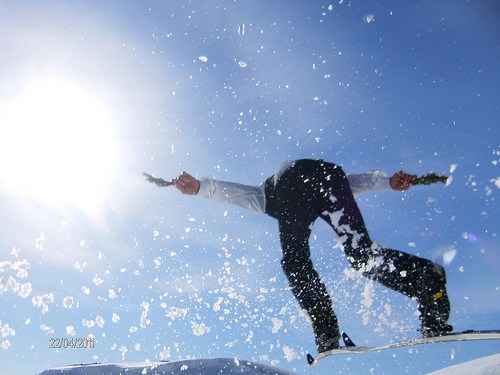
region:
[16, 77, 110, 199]
the sun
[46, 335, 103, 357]
date on the picture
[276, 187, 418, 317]
person is wearing pants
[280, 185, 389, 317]
the pants are black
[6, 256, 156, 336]
snow particles in the sky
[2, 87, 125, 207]
the sun is bright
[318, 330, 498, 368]
the ski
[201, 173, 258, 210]
white long sleeves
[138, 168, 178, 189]
person is carrying an object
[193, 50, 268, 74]
snow particles in the sky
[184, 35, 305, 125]
the sky is clear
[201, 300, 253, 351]
the sky is clear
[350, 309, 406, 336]
the sky is clear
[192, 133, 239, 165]
the sky is clear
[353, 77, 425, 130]
the sky is clear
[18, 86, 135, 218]
bright sun is shinning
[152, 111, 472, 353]
the man is skiing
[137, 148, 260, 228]
the hand of a man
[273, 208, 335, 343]
the leg of a man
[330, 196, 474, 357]
the leg of a man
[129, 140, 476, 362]
a man riding a snowboard.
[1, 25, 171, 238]
a sun in a blue sky.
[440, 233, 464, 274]
snow flying into the air.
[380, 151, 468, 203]
a right hand.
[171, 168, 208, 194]
a left hand.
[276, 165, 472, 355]
a pair of black pants.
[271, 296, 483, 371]
a board under a man's legs.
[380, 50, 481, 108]
a section of blue sky.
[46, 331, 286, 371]
a hill covered in snow.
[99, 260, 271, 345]
a section of flying snow.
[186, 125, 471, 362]
A person is skiing.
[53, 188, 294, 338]
It is snowing outside.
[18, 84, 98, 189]
The sun is shining.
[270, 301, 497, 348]
The man is on a snowboard.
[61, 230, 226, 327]
The snowflakes is white.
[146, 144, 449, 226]
The person is bend over.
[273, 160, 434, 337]
The person is wearing black pants.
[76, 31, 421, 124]
The sky is blue.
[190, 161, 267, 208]
The sleeve of the shirt is white.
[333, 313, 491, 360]
The snowboard is white.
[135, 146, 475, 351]
person doing trick on snow board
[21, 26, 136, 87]
white clouds against blue sky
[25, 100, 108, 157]
white clouds against blue sky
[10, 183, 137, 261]
white clouds against blue sky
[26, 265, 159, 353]
white clouds against blue sky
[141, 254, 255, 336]
white clouds against blue sky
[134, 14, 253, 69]
white clouds against blue sky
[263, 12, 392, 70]
white clouds against blue sky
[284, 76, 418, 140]
white clouds against blue sky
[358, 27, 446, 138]
white clouds against blue sky